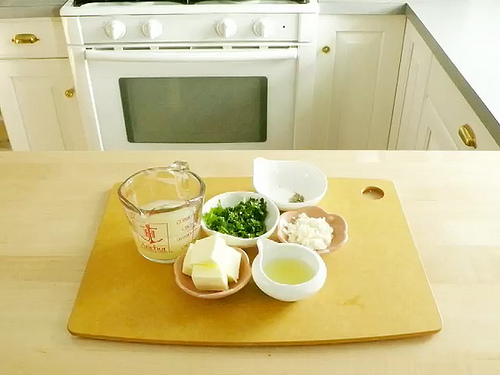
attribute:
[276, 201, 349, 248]
bowl — white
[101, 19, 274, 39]
knobs — four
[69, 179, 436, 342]
cutting board — brown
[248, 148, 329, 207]
bowl — white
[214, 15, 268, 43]
knobs — stove knobs, control knobs, white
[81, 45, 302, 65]
handle — oven door handle, metal, white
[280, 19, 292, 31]
light — power light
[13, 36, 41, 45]
handle — drawer handle, gold, metal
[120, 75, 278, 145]
window — viewing window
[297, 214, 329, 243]
onion — sliced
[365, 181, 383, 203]
hole — small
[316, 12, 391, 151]
door — kitchen cabinet door, white